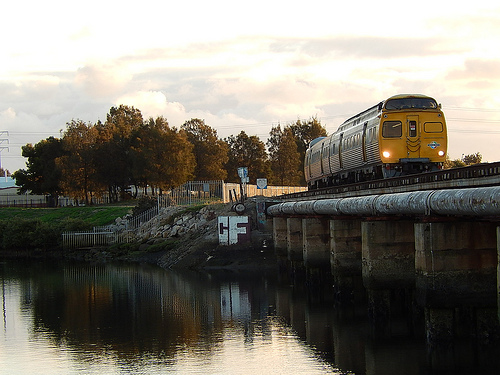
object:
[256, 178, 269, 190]
sign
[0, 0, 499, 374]
shot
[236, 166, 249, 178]
sign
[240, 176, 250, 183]
sign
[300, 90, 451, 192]
train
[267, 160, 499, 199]
tracks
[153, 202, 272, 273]
wall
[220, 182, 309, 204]
spraypaint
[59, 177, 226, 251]
fence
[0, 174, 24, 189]
building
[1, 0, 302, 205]
background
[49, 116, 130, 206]
tree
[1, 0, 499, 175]
sky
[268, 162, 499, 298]
bridge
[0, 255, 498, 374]
water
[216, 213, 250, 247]
cf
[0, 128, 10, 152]
pole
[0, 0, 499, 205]
distance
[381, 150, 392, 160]
light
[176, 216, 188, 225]
rock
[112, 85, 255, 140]
cloud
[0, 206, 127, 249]
riverbank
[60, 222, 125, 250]
gate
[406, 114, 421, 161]
door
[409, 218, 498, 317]
column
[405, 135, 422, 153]
chain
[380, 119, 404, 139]
window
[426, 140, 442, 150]
logo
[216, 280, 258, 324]
reflection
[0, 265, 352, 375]
reflection